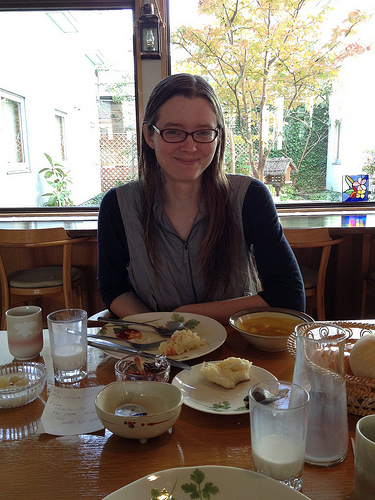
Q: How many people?
A: One.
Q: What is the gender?
A: Female.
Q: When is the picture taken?
A: Daytime.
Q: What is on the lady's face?
A: Glasses.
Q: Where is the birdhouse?
A: In the tree.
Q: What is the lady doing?
A: Sitting.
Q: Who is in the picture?
A: A lady.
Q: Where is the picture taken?
A: At a restaurant.